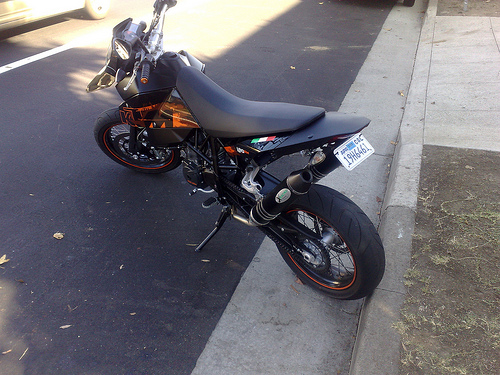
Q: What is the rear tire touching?
A: Curb.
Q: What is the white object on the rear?
A: License plate.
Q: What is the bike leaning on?
A: Kickstant.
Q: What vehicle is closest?
A: Motorcycle.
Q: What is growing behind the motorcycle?
A: Grass.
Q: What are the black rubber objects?
A: Tires.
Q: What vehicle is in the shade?
A: Motorcycle.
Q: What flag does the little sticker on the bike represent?
A: Italy.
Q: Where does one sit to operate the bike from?
A: Seat.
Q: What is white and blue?
A: License plate.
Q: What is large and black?
A: The bike.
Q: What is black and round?
A: The bike.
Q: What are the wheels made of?
A: Rubber.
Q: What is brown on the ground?
A: Dirt.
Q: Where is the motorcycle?
A: On the street.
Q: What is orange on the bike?
A: The design.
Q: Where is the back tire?
A: Against the curb.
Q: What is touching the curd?
A: Back wheel.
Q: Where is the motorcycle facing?
A: To the left.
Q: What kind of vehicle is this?
A: Motorcycle.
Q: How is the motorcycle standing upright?
A: Kickstand.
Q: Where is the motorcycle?
A: Street.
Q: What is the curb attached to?
A: Sidewalk.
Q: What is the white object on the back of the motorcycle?
A: License plate.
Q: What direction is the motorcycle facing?
A: Left.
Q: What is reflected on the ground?
A: Shadow.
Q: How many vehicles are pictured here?
A: One.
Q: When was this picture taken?
A: Daytime.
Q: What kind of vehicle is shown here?
A: Motorcycle.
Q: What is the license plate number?
A: 19H6461.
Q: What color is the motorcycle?
A: Black.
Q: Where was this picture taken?
A: A street.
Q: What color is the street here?
A: Black.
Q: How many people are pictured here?
A: Zero.